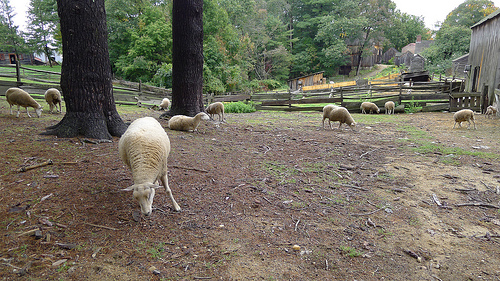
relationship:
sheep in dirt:
[119, 116, 181, 216] [0, 97, 499, 280]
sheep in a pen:
[119, 116, 181, 216] [1, 63, 500, 280]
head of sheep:
[122, 182, 164, 216] [119, 116, 181, 216]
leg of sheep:
[161, 174, 181, 211] [119, 116, 181, 216]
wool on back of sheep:
[141, 121, 152, 132] [119, 116, 181, 216]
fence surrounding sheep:
[1, 61, 468, 112] [119, 116, 181, 216]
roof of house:
[0, 38, 31, 47] [1, 47, 44, 65]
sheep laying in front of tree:
[168, 112, 211, 133] [40, 0, 127, 138]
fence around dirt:
[1, 61, 468, 112] [0, 97, 499, 280]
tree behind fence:
[355, 0, 398, 76] [1, 61, 468, 112]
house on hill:
[1, 47, 44, 65] [1, 65, 81, 85]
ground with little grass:
[0, 97, 453, 278] [221, 100, 454, 250]